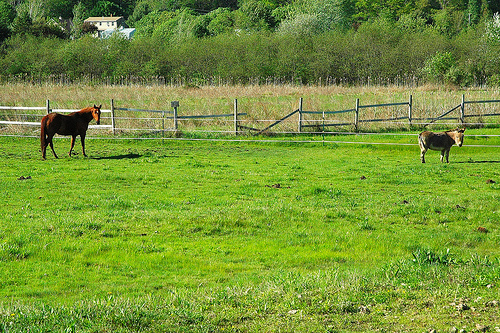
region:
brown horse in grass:
[38, 105, 103, 157]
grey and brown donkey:
[417, 127, 465, 163]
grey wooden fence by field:
[3, 97, 499, 129]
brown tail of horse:
[38, 113, 49, 155]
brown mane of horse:
[71, 107, 98, 112]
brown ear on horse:
[91, 104, 97, 109]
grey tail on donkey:
[418, 133, 425, 150]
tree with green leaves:
[189, 7, 267, 39]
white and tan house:
[86, 14, 134, 39]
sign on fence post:
[170, 101, 181, 111]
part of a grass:
[291, 215, 299, 249]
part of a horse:
[396, 176, 402, 182]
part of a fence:
[297, 130, 302, 157]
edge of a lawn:
[281, 215, 288, 236]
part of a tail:
[413, 138, 421, 148]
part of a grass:
[350, 190, 356, 204]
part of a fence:
[274, 123, 282, 139]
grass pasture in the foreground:
[2, 130, 497, 332]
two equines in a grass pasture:
[35, 99, 462, 169]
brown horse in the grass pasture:
[37, 99, 102, 158]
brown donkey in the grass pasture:
[410, 124, 465, 167]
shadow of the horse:
[94, 144, 141, 163]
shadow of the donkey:
[454, 154, 494, 170]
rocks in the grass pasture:
[342, 277, 492, 329]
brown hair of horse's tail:
[35, 113, 47, 158]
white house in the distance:
[78, 17, 131, 41]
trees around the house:
[5, 3, 490, 28]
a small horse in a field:
[414, 124, 466, 163]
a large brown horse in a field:
[35, 102, 108, 157]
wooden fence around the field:
[1, 97, 498, 132]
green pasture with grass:
[3, 129, 496, 331]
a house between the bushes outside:
[77, 12, 139, 49]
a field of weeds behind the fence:
[1, 77, 496, 110]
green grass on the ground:
[5, 131, 497, 331]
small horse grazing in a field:
[412, 123, 477, 162]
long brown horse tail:
[35, 114, 50, 154]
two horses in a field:
[34, 106, 469, 168]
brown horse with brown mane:
[27, 98, 105, 158]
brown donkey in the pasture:
[412, 129, 470, 161]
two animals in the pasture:
[37, 101, 463, 170]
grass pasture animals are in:
[2, 137, 497, 332]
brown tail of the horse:
[37, 115, 48, 161]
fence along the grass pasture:
[6, 100, 496, 131]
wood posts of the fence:
[0, 95, 499, 130]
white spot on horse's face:
[94, 107, 100, 110]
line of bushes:
[2, 32, 499, 84]